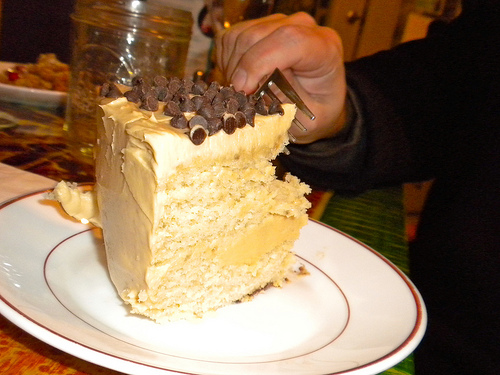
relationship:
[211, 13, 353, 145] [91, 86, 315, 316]
hand reaching for cake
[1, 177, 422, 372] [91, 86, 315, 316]
plate with cake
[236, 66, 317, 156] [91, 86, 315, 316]
fork to slice cake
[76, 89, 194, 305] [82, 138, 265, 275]
icing on cake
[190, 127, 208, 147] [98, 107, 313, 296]
chip on cake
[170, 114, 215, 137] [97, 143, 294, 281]
chip on cake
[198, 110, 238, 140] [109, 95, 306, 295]
chip on cake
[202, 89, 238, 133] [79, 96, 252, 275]
chip on cake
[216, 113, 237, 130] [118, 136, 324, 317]
chip on cake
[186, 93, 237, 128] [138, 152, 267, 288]
chip on cake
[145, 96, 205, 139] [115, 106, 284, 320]
chip on cake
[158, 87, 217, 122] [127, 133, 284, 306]
chip on cake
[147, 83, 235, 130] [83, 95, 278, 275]
chip on cake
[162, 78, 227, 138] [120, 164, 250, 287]
chip on cake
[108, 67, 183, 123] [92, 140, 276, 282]
pieces on cake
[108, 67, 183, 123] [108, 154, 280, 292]
pieces on cake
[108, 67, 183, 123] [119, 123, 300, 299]
pieces on cake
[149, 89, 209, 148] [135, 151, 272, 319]
chips on cake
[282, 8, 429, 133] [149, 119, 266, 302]
person eating cake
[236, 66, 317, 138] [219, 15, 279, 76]
fork in hand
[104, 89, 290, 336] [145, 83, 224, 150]
cake topped with kisses